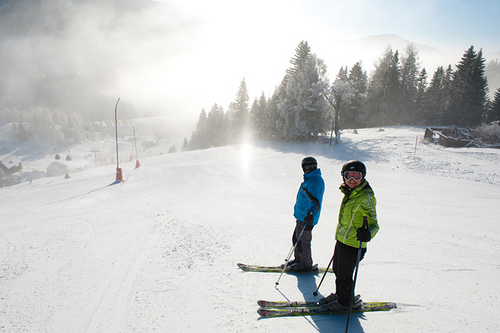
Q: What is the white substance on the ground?
A: Snow.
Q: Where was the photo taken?
A: A ski slope.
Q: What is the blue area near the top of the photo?
A: The sky.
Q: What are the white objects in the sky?
A: Clouds.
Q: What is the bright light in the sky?
A: The sun.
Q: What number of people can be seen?
A: Two.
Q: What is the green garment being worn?
A: A jacket.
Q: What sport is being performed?
A: Skiing.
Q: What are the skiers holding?
A: Ski poles.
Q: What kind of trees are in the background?
A: Pine trees.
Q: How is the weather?
A: Snowy.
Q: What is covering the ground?
A: Snow.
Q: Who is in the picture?
A: A woman and a man.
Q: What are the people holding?
A: Ski poles.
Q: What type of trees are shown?
A: Evergreen.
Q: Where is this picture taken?
A: The ski slope.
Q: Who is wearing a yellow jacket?
A: A woman.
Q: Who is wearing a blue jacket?
A: A man.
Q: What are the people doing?
A: Skiing.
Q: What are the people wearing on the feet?
A: Skis.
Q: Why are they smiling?
A: They are happy.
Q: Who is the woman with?
A: Man in blue jacket.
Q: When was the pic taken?
A: During the day.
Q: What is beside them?
A: Shadow.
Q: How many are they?
A: 2.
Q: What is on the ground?
A: Snow.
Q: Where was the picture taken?
A: At a ski area.